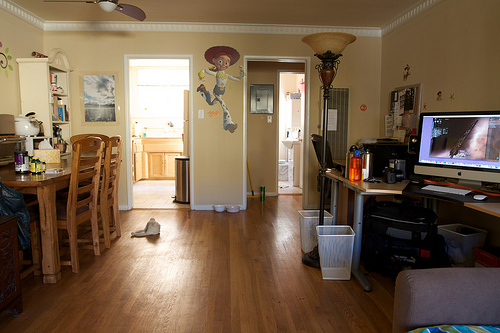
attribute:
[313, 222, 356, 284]
trash can — white mesh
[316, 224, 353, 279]
trash basket — white mesh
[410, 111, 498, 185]
tv — on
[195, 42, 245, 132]
picture — cartoon character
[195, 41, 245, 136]
decal — character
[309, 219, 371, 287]
basket — white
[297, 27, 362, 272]
lamp — floor, tall , pole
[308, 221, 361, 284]
trash can — wire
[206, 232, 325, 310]
floor — trash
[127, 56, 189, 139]
daylight — shining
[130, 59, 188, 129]
window — kitchen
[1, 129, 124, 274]
table — wooden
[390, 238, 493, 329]
couch — gray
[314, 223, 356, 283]
can — trash, white mesh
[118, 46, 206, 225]
frame — white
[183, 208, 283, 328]
floors — hard wood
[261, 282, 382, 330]
wood grain — dark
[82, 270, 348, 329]
woodgrain — dark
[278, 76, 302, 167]
light — on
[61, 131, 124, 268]
chairs — wooden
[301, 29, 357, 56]
shade — beige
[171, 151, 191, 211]
can — metal